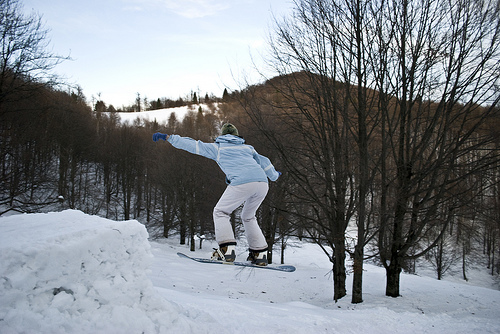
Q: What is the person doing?
A: Snowboarding.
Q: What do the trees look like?
A: Brown and leafless.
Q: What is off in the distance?
A: A hill.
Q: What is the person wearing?
A: White pants and a blue jacket.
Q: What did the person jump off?
A: A mound of snow.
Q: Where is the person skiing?
A: A hilly forest.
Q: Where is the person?
A: Midair.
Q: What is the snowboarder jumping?
A: Hill.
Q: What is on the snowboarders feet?
A: Snowboard.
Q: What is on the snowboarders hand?
A: Glove.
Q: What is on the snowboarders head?
A: Hat.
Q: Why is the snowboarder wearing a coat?
A: Cold.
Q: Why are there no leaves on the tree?
A: Winter.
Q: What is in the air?
A: Snowboarder.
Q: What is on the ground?
A: Snow.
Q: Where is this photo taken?
A: Mountains.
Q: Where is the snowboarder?
A: In air.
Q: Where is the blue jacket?
A: On the snowboarder.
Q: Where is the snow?
A: On ground.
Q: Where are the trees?
A: On the mountains.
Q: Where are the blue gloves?
A: On woman.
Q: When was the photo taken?
A: Winter.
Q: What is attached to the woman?
A: Snowboard.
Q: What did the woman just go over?
A: Snow jump.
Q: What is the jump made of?
A: Snow.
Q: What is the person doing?
A: Snowboarding.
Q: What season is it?
A: Winter.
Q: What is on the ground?
A: Snow.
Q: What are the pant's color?
A: White.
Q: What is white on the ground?
A: Snow.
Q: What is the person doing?
A: Snowboarding.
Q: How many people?
A: 1.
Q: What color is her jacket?
A: Blue.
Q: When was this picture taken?
A: Daytime.